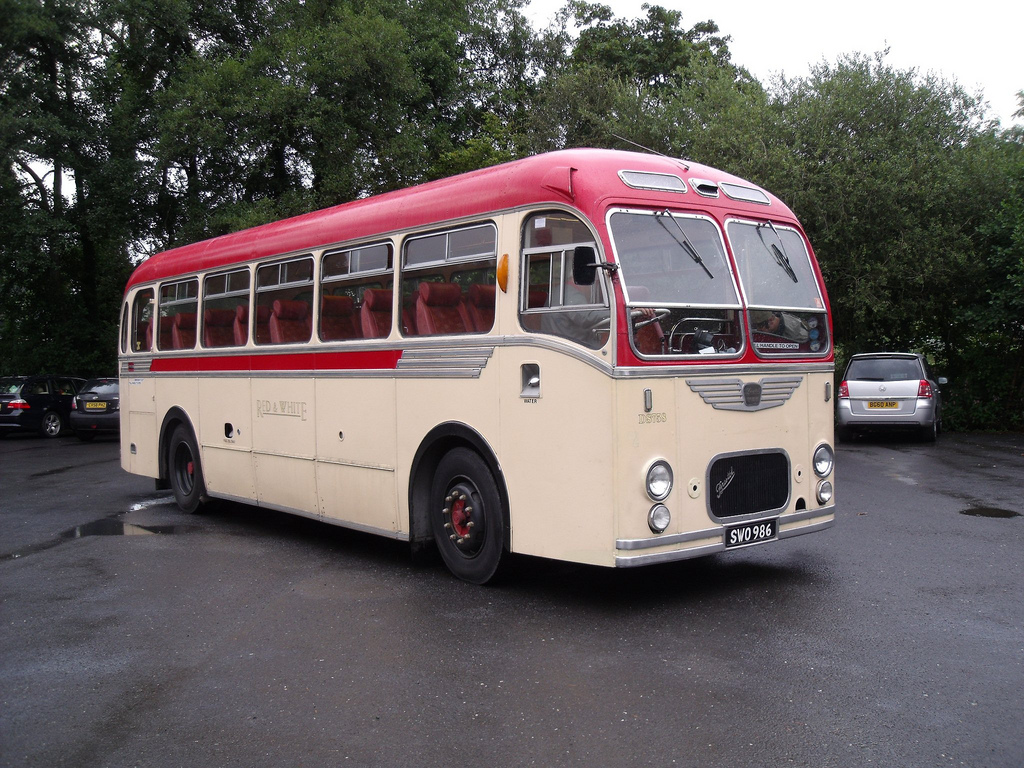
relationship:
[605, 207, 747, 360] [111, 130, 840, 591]
window of bus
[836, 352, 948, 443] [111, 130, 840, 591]
back parked behind bus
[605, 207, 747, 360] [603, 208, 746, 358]
window on window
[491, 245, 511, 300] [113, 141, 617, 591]
light on side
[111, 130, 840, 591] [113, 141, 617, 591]
bus has side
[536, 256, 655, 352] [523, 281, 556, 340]
man sitting in driver's seat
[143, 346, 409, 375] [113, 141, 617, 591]
stripe on side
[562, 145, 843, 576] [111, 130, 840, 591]
front of bus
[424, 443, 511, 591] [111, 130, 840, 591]
tire of bus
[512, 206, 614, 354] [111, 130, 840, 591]
window on bus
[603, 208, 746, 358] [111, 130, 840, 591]
window on bus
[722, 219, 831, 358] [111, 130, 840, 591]
window on bus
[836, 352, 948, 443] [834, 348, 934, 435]
back has back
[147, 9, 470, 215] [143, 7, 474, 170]
tree has leaves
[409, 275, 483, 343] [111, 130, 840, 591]
seat in bus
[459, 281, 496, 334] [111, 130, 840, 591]
seat in bus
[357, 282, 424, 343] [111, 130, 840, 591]
seat in bus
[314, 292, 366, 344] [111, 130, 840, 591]
seat in bus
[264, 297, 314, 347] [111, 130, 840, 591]
seat in bus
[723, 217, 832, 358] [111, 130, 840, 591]
window on a bus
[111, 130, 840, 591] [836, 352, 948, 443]
bus near a back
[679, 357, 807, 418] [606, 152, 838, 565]
wings on a front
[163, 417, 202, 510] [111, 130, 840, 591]
tire of bus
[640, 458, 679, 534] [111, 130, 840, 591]
light on front of bus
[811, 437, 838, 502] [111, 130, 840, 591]
light on front of bus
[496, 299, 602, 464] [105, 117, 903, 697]
wings on front of bus